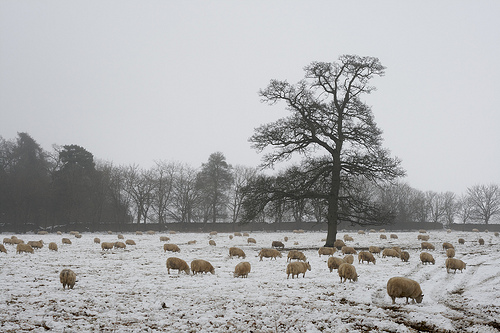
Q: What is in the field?
A: New snow.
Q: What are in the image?
A: Sheep.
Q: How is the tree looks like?
A: No leaves.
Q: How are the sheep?
A: Good.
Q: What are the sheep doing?
A: Grazing.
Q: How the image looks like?
A: Snowy.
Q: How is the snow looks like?
A: Fresh.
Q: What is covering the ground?
A: Snow.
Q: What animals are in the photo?
A: Sheep.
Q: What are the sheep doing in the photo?
A: Grazing.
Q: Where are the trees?
A: In field.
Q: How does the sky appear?
A: Cloudy.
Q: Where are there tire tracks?
A: In snow.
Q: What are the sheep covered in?
A: Wool.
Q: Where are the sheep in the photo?
A: Snowy field.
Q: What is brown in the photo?
A: Sheep and trees.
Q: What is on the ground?
A: Snow.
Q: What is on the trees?
A: Nothing.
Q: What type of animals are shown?
A: Sheep.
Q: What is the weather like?
A: Cold and dreary.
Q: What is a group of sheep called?
A: Herd.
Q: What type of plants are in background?
A: Trees.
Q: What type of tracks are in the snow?
A: Tire.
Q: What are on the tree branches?
A: No leaves.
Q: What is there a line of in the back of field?
A: Trees.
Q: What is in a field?
A: Sheep.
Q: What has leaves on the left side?
A: Trees.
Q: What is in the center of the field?
A: A tree.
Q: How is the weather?
A: Cold and overcast.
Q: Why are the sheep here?
A: They are grazing.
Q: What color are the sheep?
A: Light brown.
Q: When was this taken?
A: During the day.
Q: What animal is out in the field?
A: Sheep.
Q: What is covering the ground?
A: Snow.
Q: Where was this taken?
A: In a field.